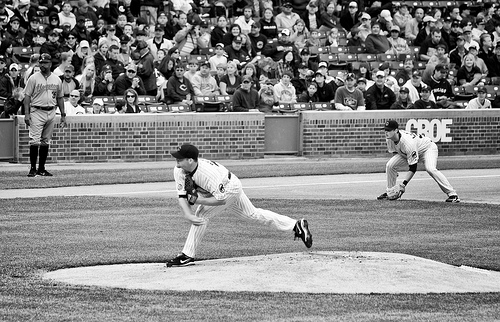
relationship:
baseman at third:
[375, 117, 463, 201] [399, 177, 491, 229]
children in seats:
[167, 22, 278, 99] [317, 51, 349, 66]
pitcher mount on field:
[42, 251, 499, 295] [44, 165, 441, 318]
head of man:
[340, 78, 396, 107] [338, 71, 369, 103]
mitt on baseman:
[385, 186, 433, 201] [375, 117, 463, 201]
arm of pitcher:
[170, 204, 221, 227] [160, 139, 313, 270]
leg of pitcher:
[237, 179, 312, 268] [160, 139, 313, 270]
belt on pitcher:
[197, 191, 224, 207] [160, 139, 313, 270]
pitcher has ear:
[160, 139, 313, 270] [181, 150, 210, 170]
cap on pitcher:
[163, 148, 204, 160] [160, 139, 313, 270]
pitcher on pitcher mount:
[160, 139, 313, 270] [42, 251, 499, 295]